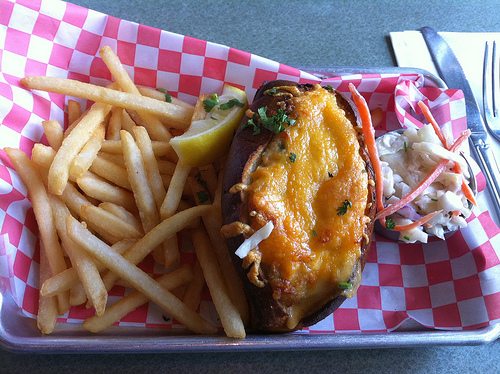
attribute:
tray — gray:
[6, 74, 498, 354]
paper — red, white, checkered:
[2, 7, 491, 329]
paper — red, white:
[134, 38, 200, 90]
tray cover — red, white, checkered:
[382, 244, 499, 332]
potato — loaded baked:
[216, 65, 381, 334]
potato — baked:
[199, 65, 379, 345]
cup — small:
[363, 118, 472, 247]